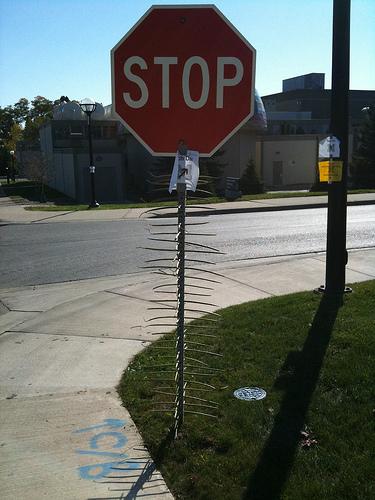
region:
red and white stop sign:
[102, 2, 262, 166]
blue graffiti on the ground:
[69, 417, 144, 479]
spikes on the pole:
[136, 153, 246, 455]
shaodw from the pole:
[89, 427, 182, 499]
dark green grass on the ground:
[117, 279, 374, 498]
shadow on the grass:
[245, 295, 361, 497]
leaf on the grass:
[297, 424, 318, 446]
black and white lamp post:
[76, 97, 110, 213]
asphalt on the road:
[0, 206, 374, 287]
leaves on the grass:
[297, 420, 315, 448]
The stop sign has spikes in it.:
[111, 1, 255, 428]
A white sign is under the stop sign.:
[103, 42, 263, 190]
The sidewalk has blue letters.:
[62, 414, 159, 485]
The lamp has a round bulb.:
[70, 95, 109, 210]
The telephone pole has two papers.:
[316, 2, 356, 200]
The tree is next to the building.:
[231, 145, 270, 196]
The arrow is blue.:
[69, 408, 133, 434]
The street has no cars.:
[54, 214, 356, 283]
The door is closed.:
[267, 155, 291, 191]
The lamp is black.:
[75, 97, 106, 209]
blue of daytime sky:
[3, 2, 372, 103]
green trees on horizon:
[1, 95, 67, 172]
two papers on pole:
[318, 0, 350, 289]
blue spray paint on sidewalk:
[74, 418, 137, 479]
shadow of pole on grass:
[237, 292, 345, 498]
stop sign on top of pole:
[109, 3, 256, 436]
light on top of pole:
[79, 96, 96, 206]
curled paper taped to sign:
[168, 144, 199, 193]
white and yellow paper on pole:
[317, 135, 343, 182]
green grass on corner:
[120, 279, 372, 498]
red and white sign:
[110, 15, 256, 169]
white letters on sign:
[70, 0, 251, 164]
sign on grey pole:
[124, 10, 239, 176]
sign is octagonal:
[109, 2, 237, 176]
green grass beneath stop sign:
[177, 263, 372, 491]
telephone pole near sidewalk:
[286, 2, 370, 287]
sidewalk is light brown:
[31, 249, 329, 498]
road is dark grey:
[7, 214, 288, 262]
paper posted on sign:
[179, 138, 203, 195]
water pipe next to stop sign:
[236, 371, 277, 409]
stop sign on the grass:
[107, 0, 256, 438]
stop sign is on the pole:
[109, 0, 252, 437]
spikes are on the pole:
[140, 154, 227, 440]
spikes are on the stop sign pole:
[109, 3, 253, 441]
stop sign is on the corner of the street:
[108, 0, 267, 440]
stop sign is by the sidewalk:
[109, 1, 262, 442]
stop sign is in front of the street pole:
[109, 0, 355, 298]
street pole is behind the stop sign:
[108, 0, 354, 297]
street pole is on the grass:
[319, 2, 354, 296]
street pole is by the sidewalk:
[311, 0, 356, 294]